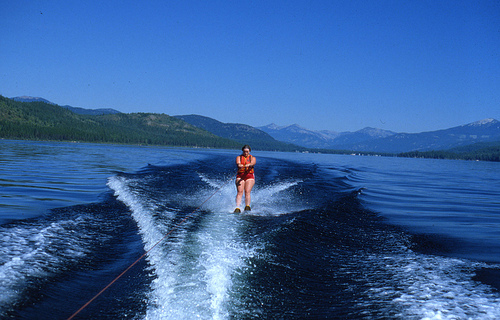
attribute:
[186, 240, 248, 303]
water — moving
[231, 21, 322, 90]
sky — blue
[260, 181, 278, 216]
waves — white